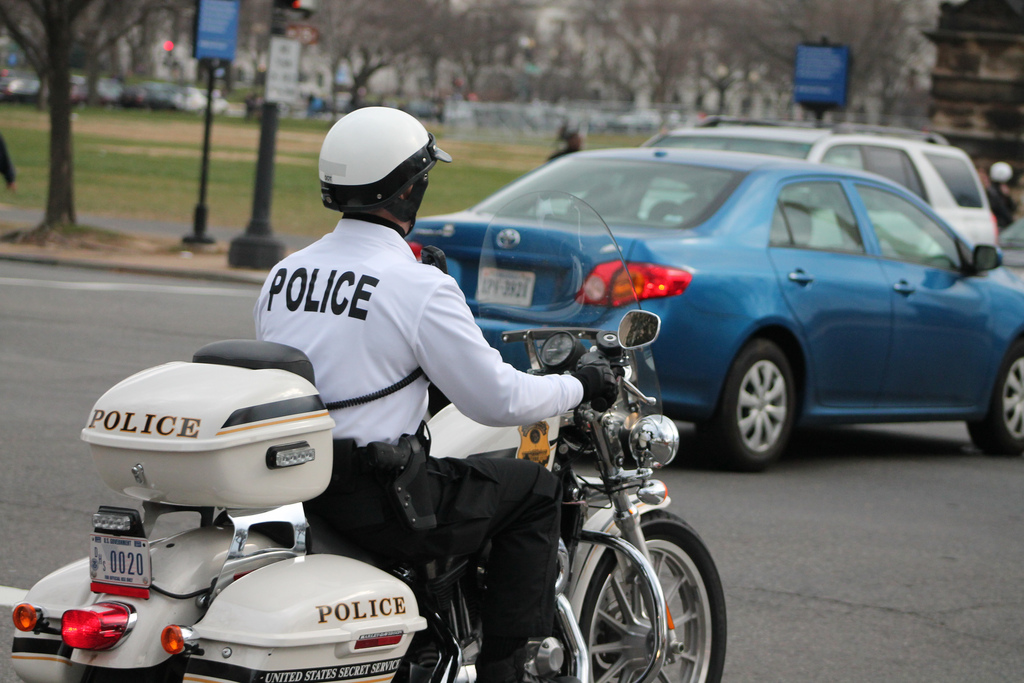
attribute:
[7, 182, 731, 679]
police motorcycle — black, white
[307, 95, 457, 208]
helmet — one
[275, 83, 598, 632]
person — one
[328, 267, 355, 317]
letter — black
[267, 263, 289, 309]
letter — black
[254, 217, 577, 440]
shirt — white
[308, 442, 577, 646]
pants — black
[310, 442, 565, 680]
pants — black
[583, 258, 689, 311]
light — red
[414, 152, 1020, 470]
car — blue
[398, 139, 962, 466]
car — blue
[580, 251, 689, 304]
tailight — red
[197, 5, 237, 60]
sign — blue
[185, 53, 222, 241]
pole — black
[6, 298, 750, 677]
motorcycle — white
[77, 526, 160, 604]
license plate — white, blue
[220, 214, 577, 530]
shirt — white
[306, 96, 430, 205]
helmet — white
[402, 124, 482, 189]
visor — black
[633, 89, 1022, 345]
suv — silver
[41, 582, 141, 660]
lights — orange, red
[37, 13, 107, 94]
branches — dead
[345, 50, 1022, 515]
car — blue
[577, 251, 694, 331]
tail light — red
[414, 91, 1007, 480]
car — blue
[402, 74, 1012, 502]
car — blue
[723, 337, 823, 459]
tire — black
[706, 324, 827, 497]
tire — black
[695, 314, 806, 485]
tire — black